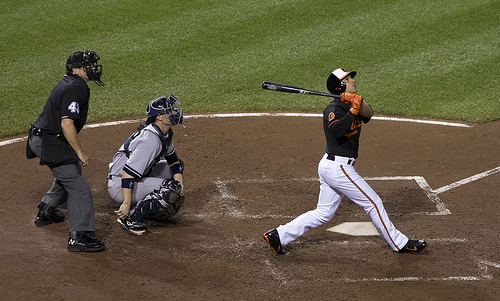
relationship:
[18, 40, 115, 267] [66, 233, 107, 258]
umpire wearing black shoe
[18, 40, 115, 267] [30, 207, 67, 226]
umpire wearing black shoe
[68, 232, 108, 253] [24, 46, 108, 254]
black shoe of umpire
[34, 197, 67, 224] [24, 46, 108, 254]
black shoe of umpire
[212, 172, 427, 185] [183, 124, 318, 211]
line on dirt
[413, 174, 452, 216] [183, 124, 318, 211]
line on dirt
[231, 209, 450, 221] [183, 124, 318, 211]
line on dirt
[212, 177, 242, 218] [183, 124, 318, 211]
line on dirt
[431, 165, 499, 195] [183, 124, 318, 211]
line on dirt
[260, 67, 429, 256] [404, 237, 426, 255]
batter wearing shoe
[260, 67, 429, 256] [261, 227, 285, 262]
batter wearing shoe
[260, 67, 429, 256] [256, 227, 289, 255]
batter wearing shoe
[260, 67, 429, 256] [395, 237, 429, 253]
batter wearing black shoe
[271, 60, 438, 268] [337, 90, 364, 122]
batter has gloves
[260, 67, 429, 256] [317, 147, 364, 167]
batter has belt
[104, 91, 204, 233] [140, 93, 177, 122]
catcher has helmet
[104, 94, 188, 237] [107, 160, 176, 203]
catcher has pants